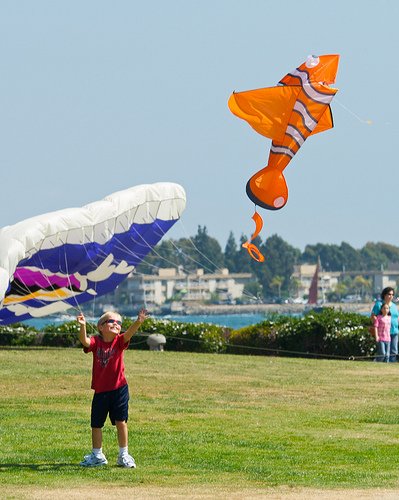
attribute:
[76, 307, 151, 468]
boy — little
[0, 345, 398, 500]
grass — cut, short, green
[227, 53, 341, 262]
kite — fish, orange, clown fish, flying, white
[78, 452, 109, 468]
shoe — white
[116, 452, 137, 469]
shoe — white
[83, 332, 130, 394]
shirt — red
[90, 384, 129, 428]
shorts — dark, blue, pair, black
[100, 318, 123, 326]
sunglasses — red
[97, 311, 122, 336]
hair — blond, blonde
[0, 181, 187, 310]
edge — white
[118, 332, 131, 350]
sleeve — short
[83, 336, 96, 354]
sleeve — short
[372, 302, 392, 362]
girl — pink, little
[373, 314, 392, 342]
shirt — pink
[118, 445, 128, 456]
sock — white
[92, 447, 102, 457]
sock — white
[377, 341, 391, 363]
jeans — blue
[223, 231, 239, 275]
top — tree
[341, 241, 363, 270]
top — tree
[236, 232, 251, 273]
top — tree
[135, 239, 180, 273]
top — tree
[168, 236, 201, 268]
top — tree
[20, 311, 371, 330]
water — blue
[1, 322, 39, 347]
bush — green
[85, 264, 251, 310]
building — white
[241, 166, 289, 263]
tail — orange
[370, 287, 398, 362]
woman — blue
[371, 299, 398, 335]
shirt — large, blue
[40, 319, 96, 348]
bush — green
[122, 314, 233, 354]
bush — green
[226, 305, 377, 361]
bush — green